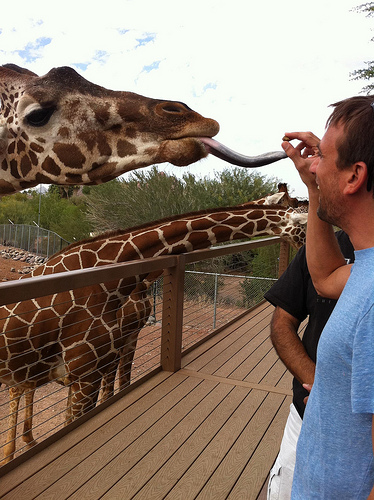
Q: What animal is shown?
A: A giraffe.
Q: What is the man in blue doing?
A: Feeding a giraffe.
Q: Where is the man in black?
A: Next to the man in blue.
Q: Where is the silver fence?
A: To the left of the giraffe.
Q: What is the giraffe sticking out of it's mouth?
A: It's tongue.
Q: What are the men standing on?
A: A deck.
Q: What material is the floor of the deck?
A: Wood.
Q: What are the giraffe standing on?
A: Dirt.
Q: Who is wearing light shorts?
A: The man in the black shirt.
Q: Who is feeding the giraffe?
A: A young man.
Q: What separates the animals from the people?
A: A fence.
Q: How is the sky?
A: Cloudy with patches of blue.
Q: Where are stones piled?
A: Along the chain link fence.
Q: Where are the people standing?
A: On a wooden deck.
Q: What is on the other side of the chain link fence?
A: Trees and bushes.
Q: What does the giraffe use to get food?
A: Its tongue.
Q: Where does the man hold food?
A: In this right hand.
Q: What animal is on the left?
A: A giraffe.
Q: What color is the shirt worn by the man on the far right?
A: Blue.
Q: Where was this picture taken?
A: A zoo.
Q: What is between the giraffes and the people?
A: A fence.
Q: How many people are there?
A: Two.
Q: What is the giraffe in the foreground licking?
A: The man's hand.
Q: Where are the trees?
A: Behind the fence.